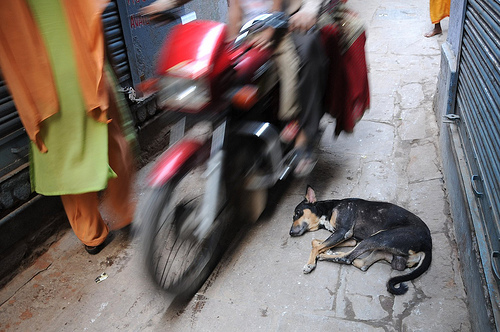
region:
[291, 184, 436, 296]
a dog laying in the street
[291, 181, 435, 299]
a black and brown dog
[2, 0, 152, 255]
a person wearing a yellow and orange outfit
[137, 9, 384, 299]
a red motorcycle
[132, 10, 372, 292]
a motorcycle driving by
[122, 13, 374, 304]
a motorcycle in motion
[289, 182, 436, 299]
a dog resting on pavement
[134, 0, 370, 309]
people on a motorcycle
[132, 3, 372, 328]
people driving a motorcycle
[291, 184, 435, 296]
a dog with its ear up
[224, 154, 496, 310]
this is a dog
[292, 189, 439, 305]
the dog looks dead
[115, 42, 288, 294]
this is a motorcycle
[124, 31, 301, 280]
the motorcycle is red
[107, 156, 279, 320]
this is a wheel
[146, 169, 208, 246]
the wheel is black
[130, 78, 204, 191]
This is a white light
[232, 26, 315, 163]
This is a handle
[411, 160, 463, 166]
This is a door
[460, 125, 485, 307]
The door is made of metal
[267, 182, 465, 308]
the dog is resting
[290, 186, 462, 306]
a black and brown dog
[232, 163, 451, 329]
dog is laying down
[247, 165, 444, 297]
dog is laying on the ground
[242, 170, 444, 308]
the dog is black and tan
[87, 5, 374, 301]
the bike is in motion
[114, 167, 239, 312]
the wheel is black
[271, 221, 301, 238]
the nose is black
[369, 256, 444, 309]
the tail is curled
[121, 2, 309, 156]
the bike is red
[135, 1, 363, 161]
man is riding the bike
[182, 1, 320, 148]
a child is getting a ride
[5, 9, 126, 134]
the scarf is orange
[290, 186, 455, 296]
the dog on the streent